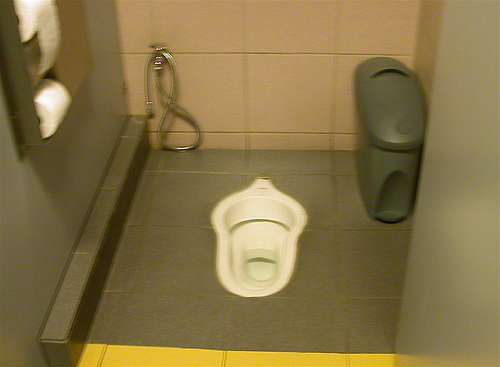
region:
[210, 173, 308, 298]
a toilet set in the ground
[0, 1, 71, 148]
a toilet paper dispenser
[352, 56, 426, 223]
a plastic trash can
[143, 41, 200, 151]
a metal hose and spray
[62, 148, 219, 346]
dark brown tile floor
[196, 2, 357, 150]
light brown tiled wall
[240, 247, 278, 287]
the toilet bowls waste water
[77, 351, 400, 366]
yellow tiled step on the floor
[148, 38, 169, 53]
the water on and off valve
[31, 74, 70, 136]
plain white toilet paper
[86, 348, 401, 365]
yellow stripe on floor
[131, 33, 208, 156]
silver faucet and hose attached to wall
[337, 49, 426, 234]
gray trash can in bathroom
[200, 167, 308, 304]
urinal on the floor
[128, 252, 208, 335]
large gray floor tiles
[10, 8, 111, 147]
built in metal toilet paper holder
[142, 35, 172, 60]
handle of faucet on wall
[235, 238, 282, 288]
water in bottom of toilet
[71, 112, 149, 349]
baseboard in toilet area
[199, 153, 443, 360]
the toilet is white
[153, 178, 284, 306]
the toilet is white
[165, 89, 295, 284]
the toilet is white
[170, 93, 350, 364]
the toilet is white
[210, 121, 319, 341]
the toilet is white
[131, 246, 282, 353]
the floor is tiled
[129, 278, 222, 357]
the floor is tiled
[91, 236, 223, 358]
the floor is tiled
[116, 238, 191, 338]
the floor is tiled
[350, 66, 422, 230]
a trash can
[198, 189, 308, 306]
a urinal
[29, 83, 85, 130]
toilet paper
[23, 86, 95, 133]
the toilet paper is white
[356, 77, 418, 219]
the trash can is grey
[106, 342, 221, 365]
tile is yellow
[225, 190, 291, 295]
the urinal is white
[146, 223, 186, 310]
the tiel is grey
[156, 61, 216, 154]
a water hose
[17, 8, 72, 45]
toilet paper